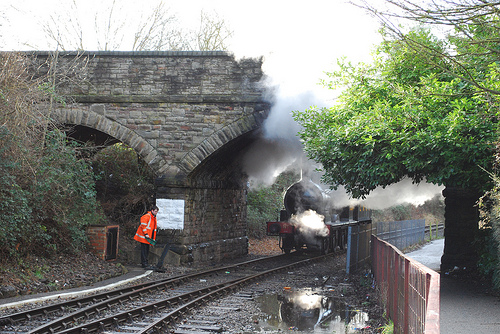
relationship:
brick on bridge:
[128, 108, 147, 120] [1, 49, 283, 276]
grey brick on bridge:
[172, 150, 190, 164] [1, 49, 283, 276]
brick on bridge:
[207, 134, 220, 149] [1, 49, 283, 276]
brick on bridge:
[170, 105, 186, 115] [1, 49, 283, 276]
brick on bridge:
[129, 110, 141, 119] [1, 49, 283, 276]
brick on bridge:
[119, 63, 130, 70] [1, 49, 283, 276]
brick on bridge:
[242, 73, 265, 82] [6, 51, 370, 265]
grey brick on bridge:
[21, 51, 277, 269] [1, 49, 283, 276]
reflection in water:
[297, 296, 353, 331] [279, 280, 374, 332]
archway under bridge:
[39, 124, 154, 274] [1, 49, 283, 276]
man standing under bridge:
[130, 202, 163, 272] [1, 45, 498, 270]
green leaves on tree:
[343, 94, 450, 154] [290, 9, 499, 203]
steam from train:
[293, 211, 328, 241] [277, 170, 351, 254]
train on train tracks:
[267, 159, 374, 254] [0, 221, 446, 333]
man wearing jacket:
[130, 202, 162, 272] [88, 187, 196, 272]